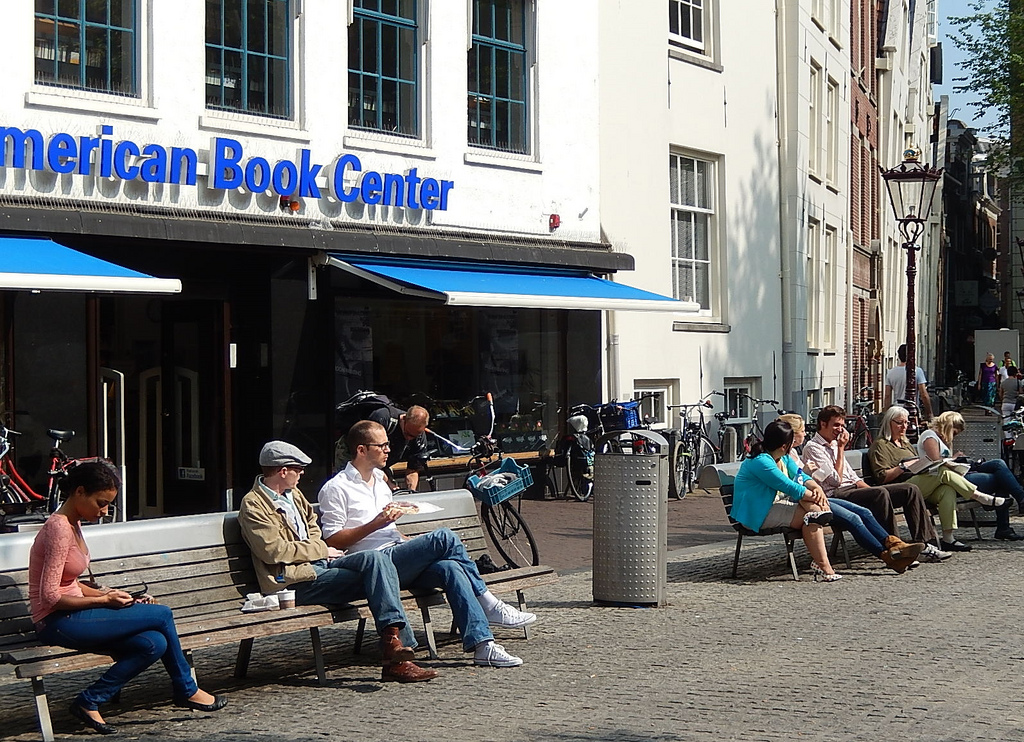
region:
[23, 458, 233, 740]
woman sitting on a wooden bench looking at a cellphone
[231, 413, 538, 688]
two men sitting beside one another on a bench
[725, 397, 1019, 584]
five people sitting on a wooden bench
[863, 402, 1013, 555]
woman sitting on the bench reading a book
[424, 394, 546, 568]
a bicycle with a blue basket in front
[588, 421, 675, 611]
silver metal trash can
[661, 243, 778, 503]
two bicycles beside a white building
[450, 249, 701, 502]
black bike in front of a store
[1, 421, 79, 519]
red bicycle with a black seat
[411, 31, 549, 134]
a view of windows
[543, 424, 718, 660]
a view of box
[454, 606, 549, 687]
a view of shoes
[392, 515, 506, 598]
a view of jeans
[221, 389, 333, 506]
a view of hat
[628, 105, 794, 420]
a view of glasses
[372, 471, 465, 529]
a view of plate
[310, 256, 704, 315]
blue awning with white frame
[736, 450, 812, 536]
woman wearing a bright turquois sweater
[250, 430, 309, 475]
men's grey flat cap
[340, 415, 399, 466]
mnan wears black rimmed glasses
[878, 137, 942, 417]
an ornate vintage street light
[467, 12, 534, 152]
windows with small panes framed in teal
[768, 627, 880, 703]
the ground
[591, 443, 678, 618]
a trash can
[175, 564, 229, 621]
the bench is brown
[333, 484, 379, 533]
man wearing a white shirt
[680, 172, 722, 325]
a window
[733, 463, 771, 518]
a blue sweater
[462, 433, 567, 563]
a bike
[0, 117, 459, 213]
letters on sign are blue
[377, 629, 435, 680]
shoes are brown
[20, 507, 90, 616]
blouse is pink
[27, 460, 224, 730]
lady is sitting on bench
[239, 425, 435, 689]
man is sitting on bench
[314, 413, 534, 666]
man is holding food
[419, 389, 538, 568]
bike has a blue basket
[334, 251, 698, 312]
awning is blue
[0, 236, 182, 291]
awning is blue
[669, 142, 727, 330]
window is above bikes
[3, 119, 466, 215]
blue letters on front of white building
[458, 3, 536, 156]
window with blue frames on building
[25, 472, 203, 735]
Woman using her phone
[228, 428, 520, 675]
Two men sitting on a bench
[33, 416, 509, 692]
Three people sitting on a bench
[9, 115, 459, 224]
Blue lettering above building.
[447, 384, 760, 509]
Row of bicycles against the wall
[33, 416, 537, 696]
Three people sat along a bench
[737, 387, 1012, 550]
Many people sitting together on a bench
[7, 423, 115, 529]
Red bicycle against the wall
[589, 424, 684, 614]
a tall gray outdoor trashcan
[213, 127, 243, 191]
a blue capital letter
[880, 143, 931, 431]
a tall street light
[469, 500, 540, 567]
the wheel of a bike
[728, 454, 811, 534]
a woman's blue sweater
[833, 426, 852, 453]
the hand of a man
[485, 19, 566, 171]
a window on the building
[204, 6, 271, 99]
a window on the building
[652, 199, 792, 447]
a window on the building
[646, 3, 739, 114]
a window on the building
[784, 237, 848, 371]
a window on the building